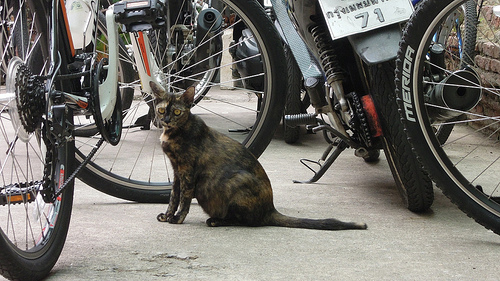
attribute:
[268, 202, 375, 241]
tail — long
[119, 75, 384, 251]
cat — brown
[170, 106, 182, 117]
cat's eye — open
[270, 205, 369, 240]
cat tail — long, brown, flat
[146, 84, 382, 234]
cat — brown, black, gold